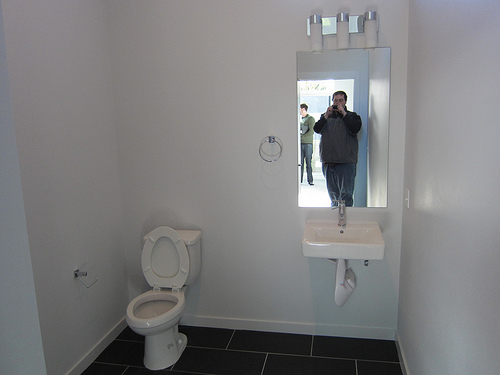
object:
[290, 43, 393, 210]
mirror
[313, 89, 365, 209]
person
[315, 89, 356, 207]
man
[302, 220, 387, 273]
sink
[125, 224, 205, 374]
toilet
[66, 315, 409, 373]
tile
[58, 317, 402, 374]
tiles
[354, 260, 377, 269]
holder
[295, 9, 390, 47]
lights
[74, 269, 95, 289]
paperholder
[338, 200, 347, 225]
faucet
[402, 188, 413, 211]
lightswitch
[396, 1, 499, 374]
wall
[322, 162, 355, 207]
pants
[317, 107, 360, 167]
coat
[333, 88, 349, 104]
hair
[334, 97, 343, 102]
glasses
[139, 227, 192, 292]
seat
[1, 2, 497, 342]
walls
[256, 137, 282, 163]
rack